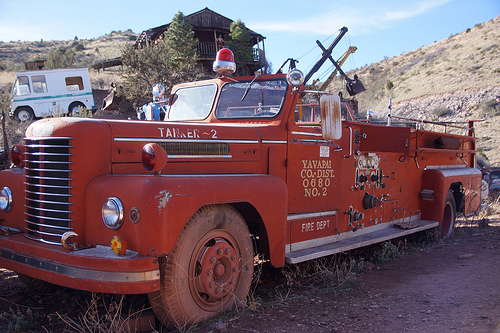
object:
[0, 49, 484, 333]
truck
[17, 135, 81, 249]
radiator area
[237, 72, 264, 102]
wipers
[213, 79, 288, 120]
window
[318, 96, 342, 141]
mirror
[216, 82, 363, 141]
wall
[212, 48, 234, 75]
base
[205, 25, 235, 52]
person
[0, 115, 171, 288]
truck`s head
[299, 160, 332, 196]
writing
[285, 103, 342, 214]
door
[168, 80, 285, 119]
front screen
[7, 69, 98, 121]
stripe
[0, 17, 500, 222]
hill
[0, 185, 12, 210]
light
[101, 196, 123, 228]
light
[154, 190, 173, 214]
scratch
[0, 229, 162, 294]
bumper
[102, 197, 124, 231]
headlight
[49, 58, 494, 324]
truck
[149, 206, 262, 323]
tire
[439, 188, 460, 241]
tire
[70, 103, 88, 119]
tire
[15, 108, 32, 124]
tire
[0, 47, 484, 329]
fire truck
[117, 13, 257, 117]
tree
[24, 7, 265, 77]
building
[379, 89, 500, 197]
rocks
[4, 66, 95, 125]
van